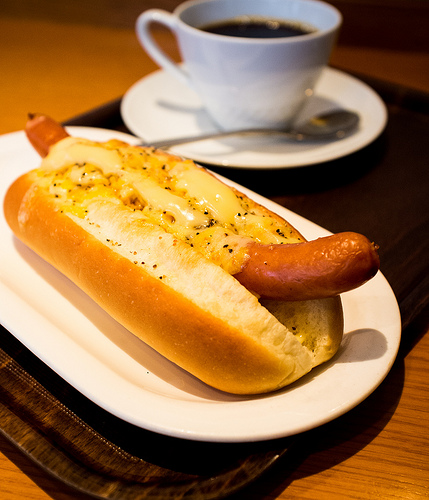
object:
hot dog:
[3, 107, 385, 404]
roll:
[2, 139, 348, 398]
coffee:
[193, 13, 320, 42]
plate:
[1, 122, 408, 450]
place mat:
[1, 31, 428, 499]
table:
[0, 0, 429, 499]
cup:
[132, 0, 343, 147]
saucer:
[115, 58, 245, 175]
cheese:
[38, 133, 281, 281]